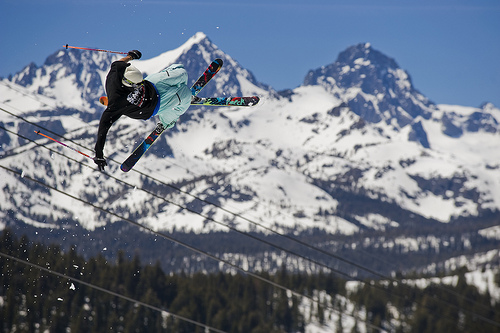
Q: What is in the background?
A: Mountains.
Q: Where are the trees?
A: Valley.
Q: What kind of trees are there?
A: Coniferous.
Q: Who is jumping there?
A: Skier.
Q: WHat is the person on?
A: Skis.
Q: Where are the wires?
A: In air.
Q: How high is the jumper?
A: Very high.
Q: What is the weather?
A: Fair.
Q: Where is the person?
A: In the air.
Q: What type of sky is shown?
A: Clear blue.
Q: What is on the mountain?
A: Snow.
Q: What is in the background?
A: Mountains.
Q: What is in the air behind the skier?
A: Wires.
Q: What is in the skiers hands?
A: Ski poles.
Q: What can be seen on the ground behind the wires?
A: Trees.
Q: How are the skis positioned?
A: Crossed.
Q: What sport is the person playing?
A: Skiing.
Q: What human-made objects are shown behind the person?
A: Wires.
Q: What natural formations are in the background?
A: Mountains.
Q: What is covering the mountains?
A: Snow.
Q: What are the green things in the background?
A: Trees.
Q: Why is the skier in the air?
A: They jumped off a ramp.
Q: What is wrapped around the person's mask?
A: Goggles.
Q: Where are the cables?
A: In air.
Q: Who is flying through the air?
A: Skier.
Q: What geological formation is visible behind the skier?
A: Mountain.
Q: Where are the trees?
A: Below the skier.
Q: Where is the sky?
A: Above the mountains.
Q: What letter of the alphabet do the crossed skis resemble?
A: Letter X.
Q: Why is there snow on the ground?
A: It is winter time.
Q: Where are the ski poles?
A: Held by skier.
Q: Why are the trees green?
A: Evergreen species.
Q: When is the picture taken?
A: Daytime.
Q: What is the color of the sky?
A: Blue.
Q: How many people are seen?
A: 1.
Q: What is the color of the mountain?
A: White.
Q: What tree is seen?
A: Pine.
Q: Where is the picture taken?
A: Ski resort.